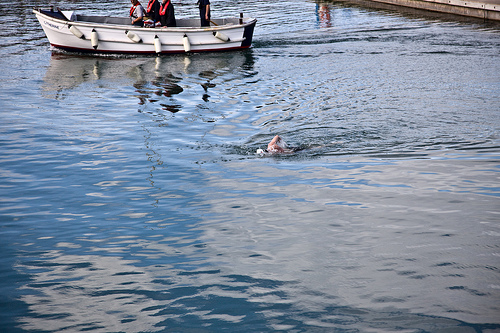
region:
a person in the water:
[236, 124, 319, 153]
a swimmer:
[236, 128, 304, 177]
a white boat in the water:
[31, 5, 305, 76]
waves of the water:
[63, 72, 218, 112]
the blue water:
[11, 203, 488, 293]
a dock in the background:
[361, 1, 488, 13]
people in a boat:
[49, 5, 276, 58]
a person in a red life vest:
[128, 2, 144, 23]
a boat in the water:
[33, 8, 259, 55]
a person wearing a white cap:
[253, 133, 290, 158]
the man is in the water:
[152, 95, 487, 327]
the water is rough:
[83, 229, 306, 329]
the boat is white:
[33, 3, 350, 75]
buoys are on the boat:
[72, 15, 352, 104]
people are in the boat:
[125, 4, 252, 59]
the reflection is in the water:
[267, 17, 425, 83]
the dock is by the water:
[402, 0, 465, 17]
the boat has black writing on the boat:
[37, 5, 86, 35]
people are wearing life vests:
[127, 4, 229, 44]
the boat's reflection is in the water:
[45, 37, 370, 204]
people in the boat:
[28, 0, 295, 75]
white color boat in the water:
[23, 24, 264, 61]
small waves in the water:
[68, 181, 444, 318]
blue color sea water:
[100, 182, 488, 317]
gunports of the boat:
[150, 33, 162, 55]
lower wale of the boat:
[103, 43, 150, 56]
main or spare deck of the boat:
[153, 20, 187, 47]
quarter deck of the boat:
[80, 21, 100, 33]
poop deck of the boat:
[33, 5, 77, 42]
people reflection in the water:
[305, 3, 340, 35]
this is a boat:
[24, 1, 279, 55]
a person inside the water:
[191, 0, 219, 32]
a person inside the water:
[151, 2, 185, 29]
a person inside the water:
[131, 0, 152, 28]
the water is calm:
[310, 132, 405, 223]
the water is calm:
[188, 191, 288, 298]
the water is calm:
[397, 46, 477, 151]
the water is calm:
[78, 162, 190, 277]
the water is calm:
[238, 238, 378, 313]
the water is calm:
[400, 125, 490, 273]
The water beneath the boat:
[8, 5, 496, 332]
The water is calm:
[1, 2, 496, 331]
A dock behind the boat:
[351, 0, 498, 23]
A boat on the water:
[33, 13, 248, 52]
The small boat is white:
[36, 10, 253, 49]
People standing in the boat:
[129, 0, 214, 27]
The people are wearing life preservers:
[148, 3, 170, 14]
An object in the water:
[253, 132, 291, 157]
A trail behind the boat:
[260, 27, 499, 53]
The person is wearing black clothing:
[197, 2, 211, 27]